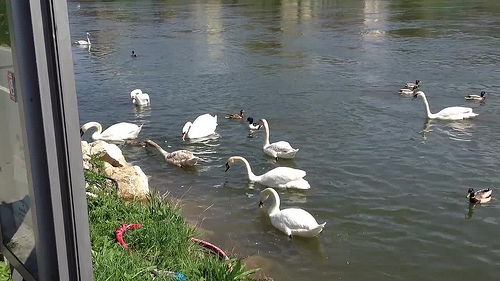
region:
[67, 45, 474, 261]
many swans in the water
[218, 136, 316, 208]
white swan with a black head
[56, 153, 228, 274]
patch of long grass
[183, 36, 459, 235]
dark ripply water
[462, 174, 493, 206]
small duck on the water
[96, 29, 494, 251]
swans and ducks swimming together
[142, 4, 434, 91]
relfections on the water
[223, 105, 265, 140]
male and female ducks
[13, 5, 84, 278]
building by the water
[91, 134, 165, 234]
large rock near the water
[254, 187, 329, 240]
a white swan in water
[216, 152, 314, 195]
a white swan in water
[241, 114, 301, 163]
a white swan in water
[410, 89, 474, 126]
a white swan in water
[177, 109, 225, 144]
a white swan in water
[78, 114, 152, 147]
a white swan in water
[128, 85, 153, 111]
a white swan in water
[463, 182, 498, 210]
a mallard duck in water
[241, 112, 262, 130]
a mallard duck in water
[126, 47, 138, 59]
a mallard duck in water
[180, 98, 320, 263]
plenty swans on lake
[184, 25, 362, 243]
plenty swans on lake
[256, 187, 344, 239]
A White Swan on the water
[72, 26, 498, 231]
A mixed Flock of Ducks and Swan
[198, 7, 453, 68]
A body of water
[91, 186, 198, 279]
Green Grass on the shore line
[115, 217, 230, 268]
Possible snake on the shore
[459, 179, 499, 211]
A duck swimming in the water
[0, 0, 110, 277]
A Grey Metal Post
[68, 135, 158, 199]
A Rock on the shore line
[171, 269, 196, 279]
Something blue hidden in the grass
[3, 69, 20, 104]
A Sticker on some glass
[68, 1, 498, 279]
calm body of water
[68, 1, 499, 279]
body of water with birds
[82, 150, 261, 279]
green patch of grass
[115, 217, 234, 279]
Round, pink object in grass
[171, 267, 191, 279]
blue object in patch of grass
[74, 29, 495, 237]
group of birds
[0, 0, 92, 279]
screen, glass door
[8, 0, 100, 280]
metal frame on door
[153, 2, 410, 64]
reflections in the water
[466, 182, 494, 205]
bird by itself to the right